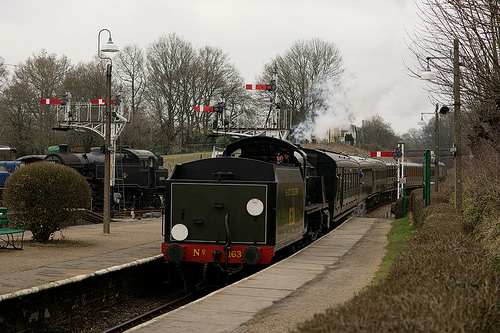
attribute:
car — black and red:
[158, 151, 312, 270]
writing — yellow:
[185, 241, 246, 259]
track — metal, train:
[80, 287, 220, 317]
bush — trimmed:
[3, 158, 99, 249]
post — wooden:
[99, 60, 116, 232]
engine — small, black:
[161, 151, 309, 269]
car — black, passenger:
[318, 146, 371, 215]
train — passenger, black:
[156, 126, 439, 263]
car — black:
[374, 160, 404, 197]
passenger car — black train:
[304, 144, 368, 233]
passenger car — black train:
[402, 160, 426, 191]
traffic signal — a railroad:
[42, 93, 127, 136]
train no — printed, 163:
[188, 243, 244, 260]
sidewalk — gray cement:
[139, 231, 359, 330]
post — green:
[423, 150, 433, 208]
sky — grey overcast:
[1, 2, 413, 53]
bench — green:
[2, 222, 28, 249]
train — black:
[158, 134, 445, 274]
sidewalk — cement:
[129, 208, 379, 331]